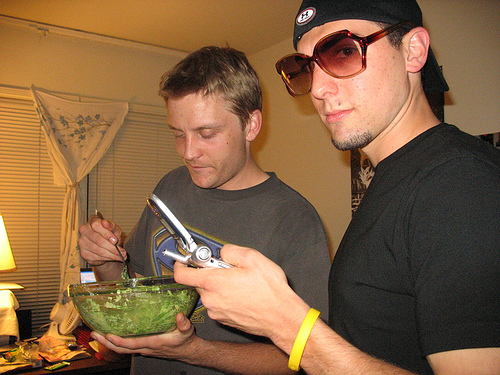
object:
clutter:
[5, 337, 96, 371]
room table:
[0, 332, 125, 374]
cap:
[290, 2, 453, 93]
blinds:
[3, 86, 194, 338]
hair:
[328, 129, 375, 152]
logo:
[295, 6, 317, 26]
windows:
[0, 84, 233, 337]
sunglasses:
[273, 20, 420, 99]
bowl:
[60, 275, 214, 338]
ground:
[447, 98, 495, 126]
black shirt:
[327, 120, 500, 374]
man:
[272, 3, 498, 373]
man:
[73, 41, 330, 371]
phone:
[143, 191, 235, 272]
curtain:
[30, 85, 131, 342]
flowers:
[94, 114, 101, 121]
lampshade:
[0, 213, 17, 272]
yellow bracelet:
[288, 306, 324, 373]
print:
[301, 10, 309, 18]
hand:
[89, 312, 197, 361]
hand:
[173, 242, 289, 342]